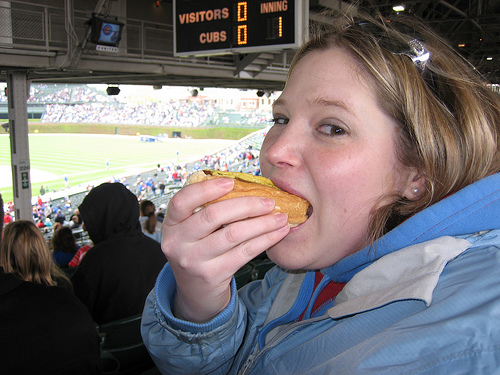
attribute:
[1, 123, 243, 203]
diamond — part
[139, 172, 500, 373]
jacket — blue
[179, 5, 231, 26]
word — lit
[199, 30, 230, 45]
word — lit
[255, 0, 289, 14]
word — lit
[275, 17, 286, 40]
number — lit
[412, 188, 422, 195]
earring — white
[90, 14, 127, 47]
tv — small